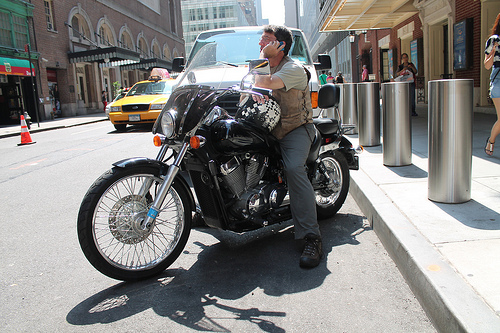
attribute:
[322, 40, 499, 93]
people — walking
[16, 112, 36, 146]
cone — orange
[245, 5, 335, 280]
person — sitting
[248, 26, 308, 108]
man — riding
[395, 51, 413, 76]
woman — standing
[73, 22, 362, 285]
man — sitting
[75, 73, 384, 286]
motorcycle — black, chrome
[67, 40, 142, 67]
awning — over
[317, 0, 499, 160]
people — walking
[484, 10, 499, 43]
hair — blonde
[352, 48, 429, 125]
people — walking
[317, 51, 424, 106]
people — walking